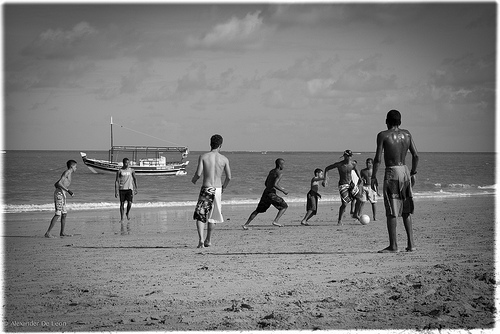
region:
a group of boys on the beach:
[43, 117, 454, 262]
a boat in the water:
[75, 111, 193, 182]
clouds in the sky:
[13, 8, 498, 130]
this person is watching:
[365, 104, 425, 257]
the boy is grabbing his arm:
[297, 160, 332, 230]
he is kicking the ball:
[320, 143, 371, 233]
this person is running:
[236, 157, 293, 232]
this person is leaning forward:
[34, 157, 76, 236]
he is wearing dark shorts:
[247, 187, 288, 221]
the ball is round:
[357, 212, 372, 225]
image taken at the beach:
[7, 6, 494, 328]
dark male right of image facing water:
[372, 105, 417, 250]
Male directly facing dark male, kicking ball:
[331, 145, 366, 220]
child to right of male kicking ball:
[297, 165, 322, 220]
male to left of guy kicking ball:
[357, 151, 373, 217]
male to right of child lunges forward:
[245, 155, 286, 225]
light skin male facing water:
[192, 135, 227, 247]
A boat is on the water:
[81, 140, 193, 177]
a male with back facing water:
[113, 157, 138, 221]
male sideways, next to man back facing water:
[45, 155, 77, 235]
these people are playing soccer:
[26, 60, 454, 277]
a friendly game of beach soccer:
[42, 119, 429, 251]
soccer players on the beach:
[41, 129, 428, 254]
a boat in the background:
[73, 111, 209, 193]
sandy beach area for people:
[25, 191, 471, 303]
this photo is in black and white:
[25, 58, 456, 287]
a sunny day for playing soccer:
[26, 57, 478, 268]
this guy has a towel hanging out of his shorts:
[193, 179, 229, 231]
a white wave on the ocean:
[16, 181, 453, 229]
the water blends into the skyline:
[17, 132, 482, 184]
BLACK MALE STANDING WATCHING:
[367, 107, 422, 257]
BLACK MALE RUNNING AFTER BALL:
[239, 155, 286, 229]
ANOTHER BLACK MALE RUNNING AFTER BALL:
[301, 168, 327, 231]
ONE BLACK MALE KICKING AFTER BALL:
[321, 149, 371, 224]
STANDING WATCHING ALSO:
[191, 135, 229, 250]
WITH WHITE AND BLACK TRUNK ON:
[186, 183, 226, 224]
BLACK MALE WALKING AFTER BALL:
[42, 155, 79, 239]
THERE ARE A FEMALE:
[113, 158, 139, 224]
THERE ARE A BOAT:
[78, 108, 190, 178]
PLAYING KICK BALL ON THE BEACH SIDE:
[5, 188, 497, 327]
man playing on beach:
[193, 134, 235, 241]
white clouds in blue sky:
[6, 23, 57, 80]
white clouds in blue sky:
[31, 59, 82, 107]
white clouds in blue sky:
[35, 87, 79, 124]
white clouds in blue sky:
[142, 27, 212, 74]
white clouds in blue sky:
[88, 60, 179, 118]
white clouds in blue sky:
[178, 57, 256, 102]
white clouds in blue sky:
[245, 90, 302, 141]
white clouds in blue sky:
[295, 26, 380, 88]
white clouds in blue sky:
[321, 89, 362, 140]